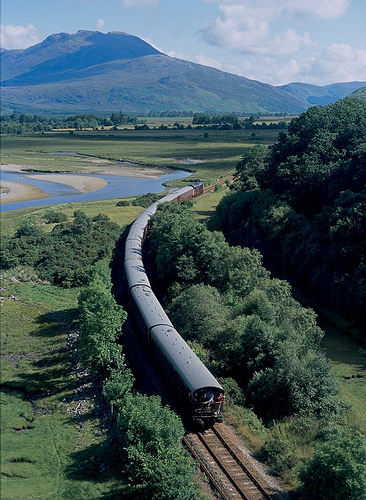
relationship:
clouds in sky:
[1, 21, 44, 55] [1, 2, 364, 86]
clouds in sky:
[199, 4, 310, 60] [1, 2, 364, 86]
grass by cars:
[1, 192, 216, 500] [123, 181, 225, 431]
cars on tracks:
[123, 181, 225, 431] [128, 165, 279, 500]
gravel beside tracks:
[62, 323, 101, 433] [128, 165, 279, 500]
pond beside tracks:
[1, 151, 198, 222] [128, 165, 279, 500]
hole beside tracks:
[336, 368, 365, 384] [128, 165, 279, 500]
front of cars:
[185, 382, 225, 429] [123, 181, 225, 431]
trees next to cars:
[143, 199, 365, 421] [123, 181, 225, 431]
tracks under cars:
[128, 165, 279, 500] [123, 181, 225, 431]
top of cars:
[132, 183, 225, 392] [123, 181, 225, 431]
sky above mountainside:
[1, 2, 364, 86] [1, 23, 365, 126]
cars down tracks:
[123, 181, 225, 431] [128, 165, 279, 500]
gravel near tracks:
[62, 323, 101, 433] [128, 165, 279, 500]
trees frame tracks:
[143, 199, 365, 421] [128, 165, 279, 500]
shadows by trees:
[6, 304, 143, 499] [143, 199, 365, 421]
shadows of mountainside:
[95, 120, 267, 169] [1, 23, 365, 126]